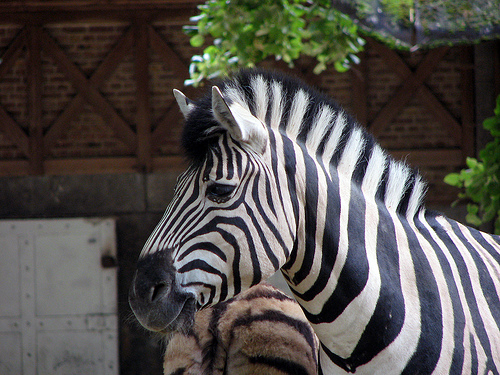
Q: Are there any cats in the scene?
A: No, there are no cats.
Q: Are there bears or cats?
A: No, there are no cats or bears.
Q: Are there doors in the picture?
A: Yes, there is a door.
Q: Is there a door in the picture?
A: Yes, there is a door.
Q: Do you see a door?
A: Yes, there is a door.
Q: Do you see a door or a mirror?
A: Yes, there is a door.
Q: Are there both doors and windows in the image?
A: No, there is a door but no windows.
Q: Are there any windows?
A: No, there are no windows.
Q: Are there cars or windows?
A: No, there are no windows or cars.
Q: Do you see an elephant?
A: No, there are no elephants.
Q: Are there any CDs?
A: No, there are no cds.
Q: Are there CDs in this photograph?
A: No, there are no cds.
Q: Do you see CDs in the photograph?
A: No, there are no cds.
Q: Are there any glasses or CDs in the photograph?
A: No, there are no CDs or glasses.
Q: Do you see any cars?
A: No, there are no cars.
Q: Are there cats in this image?
A: No, there are no cats.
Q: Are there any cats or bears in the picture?
A: No, there are no cats or bears.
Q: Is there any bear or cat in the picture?
A: No, there are no cats or bears.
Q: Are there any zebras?
A: Yes, there is a zebra.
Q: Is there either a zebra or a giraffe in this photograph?
A: Yes, there is a zebra.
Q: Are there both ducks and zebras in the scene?
A: No, there is a zebra but no ducks.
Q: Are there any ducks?
A: No, there are no ducks.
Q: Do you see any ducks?
A: No, there are no ducks.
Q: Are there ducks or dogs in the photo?
A: No, there are no ducks or dogs.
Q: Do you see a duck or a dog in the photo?
A: No, there are no ducks or dogs.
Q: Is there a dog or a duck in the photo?
A: No, there are no ducks or dogs.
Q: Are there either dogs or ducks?
A: No, there are no ducks or dogs.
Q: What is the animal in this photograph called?
A: The animal is a zebra.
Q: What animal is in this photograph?
A: The animal is a zebra.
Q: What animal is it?
A: The animal is a zebra.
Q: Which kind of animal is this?
A: This is a zebra.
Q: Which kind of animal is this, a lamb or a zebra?
A: This is a zebra.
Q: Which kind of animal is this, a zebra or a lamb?
A: This is a zebra.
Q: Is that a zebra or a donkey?
A: That is a zebra.